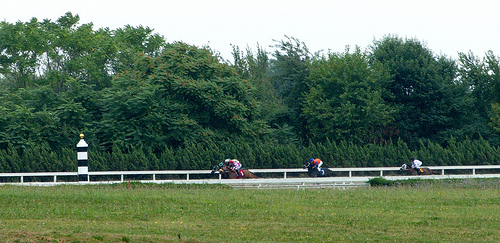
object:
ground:
[0, 176, 499, 243]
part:
[174, 191, 390, 233]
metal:
[0, 162, 498, 191]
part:
[276, 170, 299, 171]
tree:
[291, 56, 388, 143]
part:
[309, 92, 362, 121]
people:
[224, 158, 245, 179]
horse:
[219, 164, 259, 178]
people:
[309, 158, 326, 176]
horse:
[303, 161, 336, 176]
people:
[407, 158, 423, 176]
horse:
[400, 164, 434, 176]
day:
[0, 0, 499, 243]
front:
[211, 157, 257, 178]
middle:
[303, 157, 336, 177]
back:
[410, 160, 422, 170]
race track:
[0, 162, 499, 191]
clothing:
[313, 158, 324, 172]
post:
[76, 138, 89, 173]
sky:
[2, 0, 499, 85]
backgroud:
[0, 0, 499, 143]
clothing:
[411, 159, 422, 170]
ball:
[77, 133, 84, 137]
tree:
[108, 41, 260, 154]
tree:
[366, 38, 462, 153]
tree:
[10, 14, 94, 149]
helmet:
[308, 159, 315, 163]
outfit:
[219, 158, 245, 179]